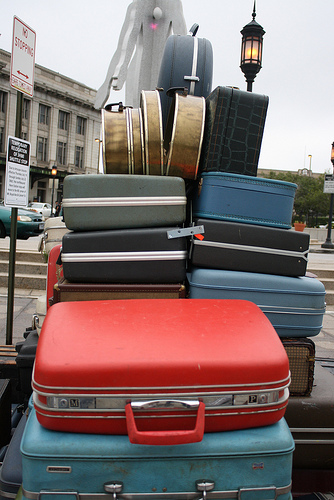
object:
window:
[38, 103, 51, 126]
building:
[0, 49, 102, 219]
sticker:
[194, 233, 205, 241]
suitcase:
[190, 217, 310, 277]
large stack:
[0, 22, 334, 500]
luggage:
[199, 85, 269, 177]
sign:
[9, 15, 36, 98]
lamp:
[240, 31, 263, 81]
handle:
[124, 398, 205, 446]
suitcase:
[60, 226, 188, 287]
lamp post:
[245, 0, 257, 94]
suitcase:
[200, 85, 270, 177]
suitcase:
[62, 173, 187, 230]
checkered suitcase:
[277, 337, 316, 398]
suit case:
[31, 299, 292, 446]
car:
[0, 204, 46, 240]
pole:
[5, 206, 18, 345]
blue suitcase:
[196, 172, 298, 230]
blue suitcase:
[185, 266, 326, 338]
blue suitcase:
[19, 393, 295, 500]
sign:
[4, 135, 32, 209]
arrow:
[16, 69, 30, 79]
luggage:
[101, 107, 145, 175]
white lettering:
[4, 135, 31, 209]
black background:
[7, 137, 30, 166]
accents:
[47, 388, 279, 410]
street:
[0, 201, 44, 355]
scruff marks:
[17, 432, 295, 489]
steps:
[0, 247, 48, 291]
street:
[311, 249, 334, 367]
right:
[275, 67, 309, 116]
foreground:
[0, 447, 334, 500]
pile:
[19, 263, 327, 500]